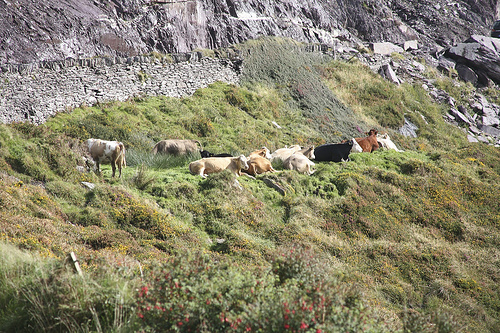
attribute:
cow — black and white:
[304, 137, 364, 160]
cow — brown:
[347, 132, 378, 152]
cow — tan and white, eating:
[79, 138, 126, 178]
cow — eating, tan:
[151, 137, 203, 157]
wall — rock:
[14, 48, 238, 118]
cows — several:
[76, 133, 398, 181]